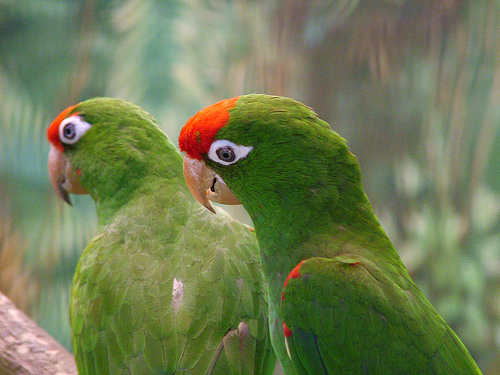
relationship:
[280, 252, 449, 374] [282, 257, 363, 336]
wing has some red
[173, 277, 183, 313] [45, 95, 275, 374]
white spot on bird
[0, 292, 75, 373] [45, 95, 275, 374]
branch under bird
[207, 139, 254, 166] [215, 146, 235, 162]
white area around eye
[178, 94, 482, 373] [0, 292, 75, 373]
bird on branch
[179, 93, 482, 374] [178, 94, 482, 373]
feathers on bird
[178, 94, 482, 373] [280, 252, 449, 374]
bird has a wing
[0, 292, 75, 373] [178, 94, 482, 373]
branch under bird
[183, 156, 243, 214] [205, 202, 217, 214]
beak has a tip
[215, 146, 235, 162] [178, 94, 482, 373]
eye on bird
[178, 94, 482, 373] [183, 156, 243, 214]
bird has a beak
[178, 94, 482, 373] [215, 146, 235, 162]
bird has an eye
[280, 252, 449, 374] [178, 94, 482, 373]
wing on bird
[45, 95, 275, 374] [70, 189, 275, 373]
bird has a back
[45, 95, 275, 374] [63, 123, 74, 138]
bird has an eye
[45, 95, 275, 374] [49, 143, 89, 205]
bird has a beak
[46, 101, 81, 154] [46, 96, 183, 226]
red on head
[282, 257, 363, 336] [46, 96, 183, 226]
red on head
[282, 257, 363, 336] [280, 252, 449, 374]
red on wing